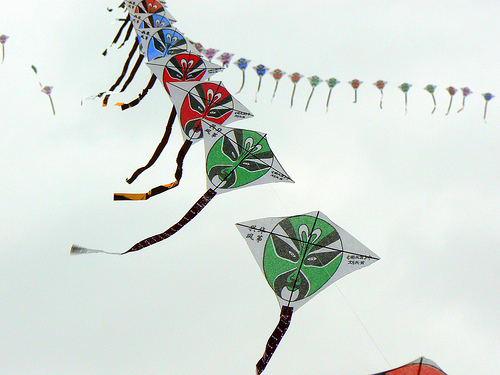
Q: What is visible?
A: A kite.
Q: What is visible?
A: A kite.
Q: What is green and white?
A: A kite.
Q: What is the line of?
A: Kites.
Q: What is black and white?
A: Kite tail.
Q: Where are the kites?
A: In the air.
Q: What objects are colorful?
A: The kites.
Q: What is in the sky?
A: The kites.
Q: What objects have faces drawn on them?
A: The kites.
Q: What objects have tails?
A: The kites.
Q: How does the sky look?
A: Gray and cloudy.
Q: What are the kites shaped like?
A: Diamonds.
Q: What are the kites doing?
A: Flying in the air.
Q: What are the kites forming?
A: A line.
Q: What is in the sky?
A: The kites.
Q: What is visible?
A: A kite.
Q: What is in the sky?
A: Kites.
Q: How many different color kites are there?
A: 3.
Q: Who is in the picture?
A: No one.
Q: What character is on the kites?
A: Power rangers.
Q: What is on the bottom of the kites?
A: Tails.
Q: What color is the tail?
A: Black.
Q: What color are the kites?
A: Green, red and bue.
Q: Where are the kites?
A: In the sky.